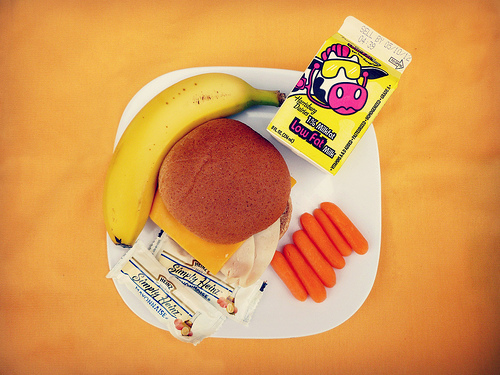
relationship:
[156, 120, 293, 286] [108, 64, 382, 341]
sandwich on plate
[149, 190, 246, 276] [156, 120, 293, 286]
cheese on sandwich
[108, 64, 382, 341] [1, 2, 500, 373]
plate on table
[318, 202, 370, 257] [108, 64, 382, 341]
carrot on plate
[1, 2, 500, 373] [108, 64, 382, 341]
table under plate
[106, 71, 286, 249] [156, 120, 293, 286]
banana with sandwich